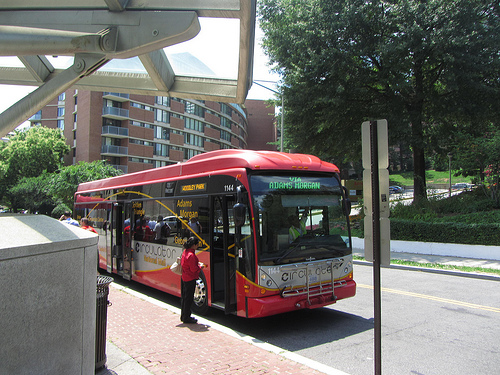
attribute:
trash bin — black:
[97, 272, 112, 370]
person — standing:
[179, 234, 203, 324]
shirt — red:
[179, 250, 203, 283]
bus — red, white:
[73, 148, 358, 318]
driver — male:
[290, 206, 310, 242]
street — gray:
[207, 263, 498, 374]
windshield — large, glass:
[248, 191, 353, 265]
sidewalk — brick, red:
[105, 280, 350, 373]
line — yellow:
[356, 280, 500, 309]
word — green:
[269, 175, 323, 190]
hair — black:
[185, 237, 200, 249]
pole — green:
[369, 119, 384, 372]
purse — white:
[171, 255, 183, 281]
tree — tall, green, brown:
[258, 2, 500, 207]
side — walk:
[106, 283, 348, 375]